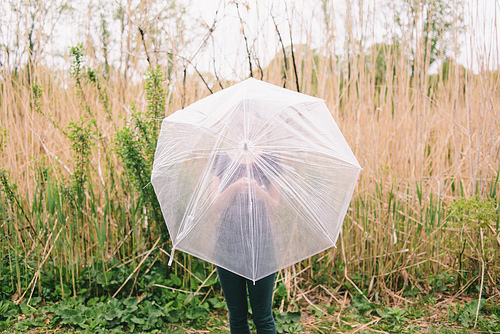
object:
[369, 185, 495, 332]
plants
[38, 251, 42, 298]
sticks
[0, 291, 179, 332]
plant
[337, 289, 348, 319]
twig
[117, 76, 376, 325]
front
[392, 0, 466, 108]
tree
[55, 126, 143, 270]
weeds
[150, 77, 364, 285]
umbrella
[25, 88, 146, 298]
bushes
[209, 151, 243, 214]
arm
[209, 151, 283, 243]
shirt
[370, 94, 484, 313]
grass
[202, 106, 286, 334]
girl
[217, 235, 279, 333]
jeans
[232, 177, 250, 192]
hands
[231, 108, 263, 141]
face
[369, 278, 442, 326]
weeds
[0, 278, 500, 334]
ground